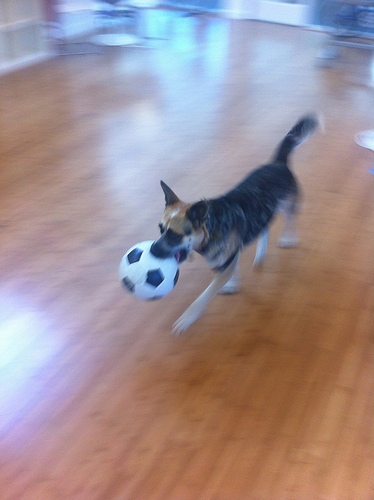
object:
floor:
[0, 6, 374, 500]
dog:
[148, 108, 321, 340]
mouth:
[148, 244, 188, 265]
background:
[0, 0, 374, 190]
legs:
[250, 223, 268, 271]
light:
[53, 0, 229, 49]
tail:
[268, 109, 324, 164]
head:
[149, 180, 210, 266]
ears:
[184, 196, 212, 231]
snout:
[149, 234, 172, 259]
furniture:
[302, 0, 373, 40]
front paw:
[170, 318, 188, 338]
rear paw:
[275, 235, 299, 249]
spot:
[169, 208, 180, 220]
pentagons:
[145, 266, 165, 288]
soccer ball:
[118, 238, 181, 305]